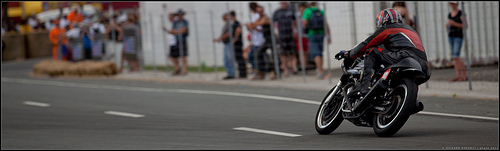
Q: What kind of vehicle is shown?
A: Motorcycle.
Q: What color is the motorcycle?
A: Black.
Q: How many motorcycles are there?
A: 1.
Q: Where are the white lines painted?
A: On the road.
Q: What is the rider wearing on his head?
A: Helmet.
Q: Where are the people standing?
A: Behind the fencing.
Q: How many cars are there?
A: None.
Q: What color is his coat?
A: Red and black.